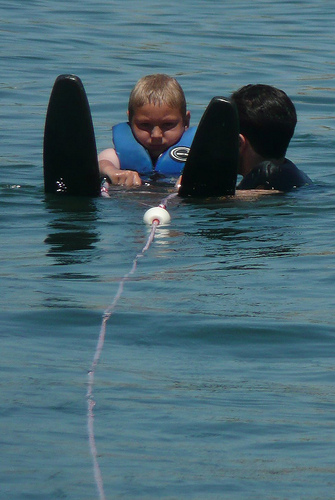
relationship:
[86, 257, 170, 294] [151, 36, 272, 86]
rope under water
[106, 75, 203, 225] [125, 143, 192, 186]
boy in life vest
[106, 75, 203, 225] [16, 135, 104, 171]
boy in skis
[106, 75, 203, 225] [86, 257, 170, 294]
boy holding rope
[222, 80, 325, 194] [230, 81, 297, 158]
person with short hair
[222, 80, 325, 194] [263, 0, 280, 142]
person with short hair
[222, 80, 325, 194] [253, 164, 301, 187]
person in black top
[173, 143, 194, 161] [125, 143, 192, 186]
logo on life vest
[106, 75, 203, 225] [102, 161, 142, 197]
boy with right hand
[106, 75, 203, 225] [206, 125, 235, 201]
boy in water ski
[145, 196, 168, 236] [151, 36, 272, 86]
buoy in water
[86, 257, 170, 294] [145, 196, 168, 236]
rope with buoy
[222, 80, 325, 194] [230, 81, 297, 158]
person has short hair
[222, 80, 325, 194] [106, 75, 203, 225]
person looking at boy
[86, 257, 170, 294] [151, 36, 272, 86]
rope in water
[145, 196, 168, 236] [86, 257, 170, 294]
buoy on rope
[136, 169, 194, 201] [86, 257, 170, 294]
handle on rope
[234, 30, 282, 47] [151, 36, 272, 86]
ripples in water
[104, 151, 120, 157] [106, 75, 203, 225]
arm of boy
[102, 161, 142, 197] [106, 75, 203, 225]
right hand of boy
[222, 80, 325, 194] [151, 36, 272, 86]
person in water